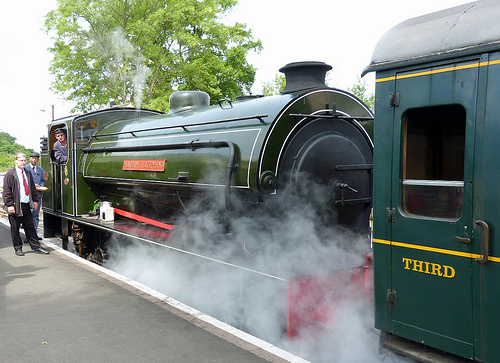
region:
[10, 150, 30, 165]
head of a person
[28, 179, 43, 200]
arm of a person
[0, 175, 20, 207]
arm of a person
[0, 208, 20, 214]
hand of a person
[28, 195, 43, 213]
hand of a person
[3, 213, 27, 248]
leg of a person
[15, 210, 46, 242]
leg of a person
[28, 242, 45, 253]
feet of a person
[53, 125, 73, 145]
head of a person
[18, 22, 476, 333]
this is at a train platform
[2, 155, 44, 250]
this is a man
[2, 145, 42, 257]
the man has a tie on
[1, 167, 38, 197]
the man's tie is red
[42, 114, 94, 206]
this is the conductor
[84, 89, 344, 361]
this is the train engine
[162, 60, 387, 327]
the train engine is green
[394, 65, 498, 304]
the train car is green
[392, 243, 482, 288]
this car says "third"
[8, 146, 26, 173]
head of a person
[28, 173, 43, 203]
arm of a person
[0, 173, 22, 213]
arm of a person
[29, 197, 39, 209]
hand of a person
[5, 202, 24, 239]
leg of a person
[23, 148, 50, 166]
head of a person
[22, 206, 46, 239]
leg of a person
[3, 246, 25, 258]
feet of a person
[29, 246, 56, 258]
feet of a person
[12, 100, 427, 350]
this is a train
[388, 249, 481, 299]
a word on a train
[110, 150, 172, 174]
a word on a train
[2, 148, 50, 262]
this is a person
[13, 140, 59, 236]
this is a person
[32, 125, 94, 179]
this is a person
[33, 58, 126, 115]
this is a branch of a tree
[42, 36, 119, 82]
this is a branch of a tree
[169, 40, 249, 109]
this is a branch of a tree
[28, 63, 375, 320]
the train is an antique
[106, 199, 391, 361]
vapor is coming out of the train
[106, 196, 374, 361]
steam is coming out of the train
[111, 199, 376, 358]
steam is coming out of the train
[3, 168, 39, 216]
a man is wearing a jacket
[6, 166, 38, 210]
the jacket is black in color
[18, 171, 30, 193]
the man is wearing a tie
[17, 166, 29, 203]
the man is wearing a white shirt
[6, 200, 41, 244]
the man is wearing long pants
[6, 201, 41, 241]
the pants are black in color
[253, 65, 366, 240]
front of train is round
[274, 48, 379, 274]
front of train is black in color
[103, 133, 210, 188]
train has red sign on it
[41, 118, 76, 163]
man is driving the train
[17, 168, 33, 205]
man is wearing a tie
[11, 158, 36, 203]
tie is red in color